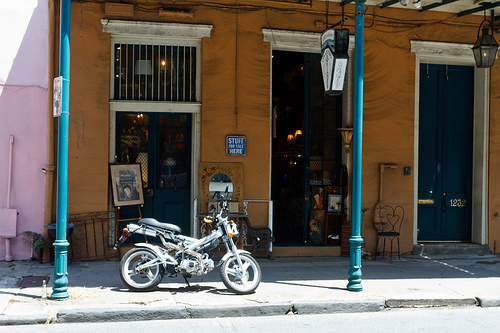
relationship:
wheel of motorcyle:
[119, 246, 166, 295] [112, 188, 263, 296]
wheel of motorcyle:
[220, 250, 263, 295] [112, 188, 263, 296]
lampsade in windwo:
[133, 60, 157, 76] [103, 19, 210, 241]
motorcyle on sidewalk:
[112, 188, 263, 296] [2, 254, 499, 325]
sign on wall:
[227, 135, 248, 153] [209, 28, 269, 161]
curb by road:
[4, 296, 499, 322] [5, 307, 499, 331]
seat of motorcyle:
[139, 215, 181, 233] [112, 188, 263, 296]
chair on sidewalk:
[375, 204, 405, 260] [2, 254, 499, 325]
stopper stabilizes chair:
[381, 256, 390, 259] [375, 204, 405, 260]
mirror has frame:
[206, 171, 237, 200] [198, 163, 243, 210]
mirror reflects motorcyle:
[206, 171, 237, 200] [112, 188, 263, 296]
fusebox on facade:
[1, 210, 18, 238] [0, 1, 50, 260]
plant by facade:
[19, 229, 46, 260] [0, 1, 50, 260]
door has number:
[417, 65, 474, 240] [449, 198, 467, 207]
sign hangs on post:
[320, 27, 351, 94] [348, 5, 365, 294]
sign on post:
[320, 27, 351, 94] [348, 5, 365, 294]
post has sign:
[348, 5, 365, 294] [320, 27, 351, 94]